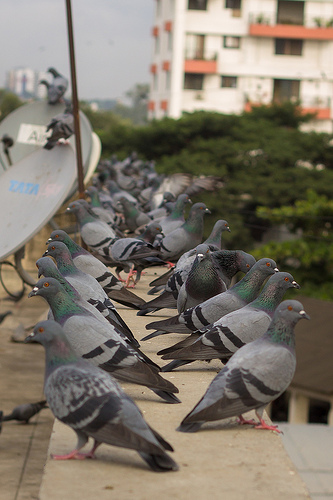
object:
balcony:
[183, 56, 218, 73]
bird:
[8, 320, 181, 473]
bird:
[36, 254, 161, 374]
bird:
[43, 240, 161, 370]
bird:
[45, 229, 149, 310]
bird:
[28, 278, 184, 404]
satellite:
[0, 96, 91, 287]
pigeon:
[141, 259, 281, 341]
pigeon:
[176, 243, 231, 317]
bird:
[175, 300, 309, 435]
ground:
[301, 116, 313, 135]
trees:
[183, 109, 328, 226]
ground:
[279, 123, 284, 134]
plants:
[247, 12, 332, 32]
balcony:
[251, 22, 332, 38]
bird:
[156, 270, 301, 371]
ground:
[252, 117, 274, 136]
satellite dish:
[0, 96, 86, 262]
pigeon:
[35, 66, 69, 106]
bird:
[176, 244, 227, 314]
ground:
[240, 48, 287, 77]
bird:
[96, 234, 167, 288]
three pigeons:
[143, 255, 304, 438]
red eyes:
[265, 261, 270, 267]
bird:
[26, 152, 310, 474]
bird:
[41, 100, 97, 150]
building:
[144, 0, 330, 141]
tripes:
[57, 391, 127, 440]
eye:
[284, 277, 288, 282]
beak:
[291, 280, 298, 284]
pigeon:
[35, 253, 128, 349]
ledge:
[36, 168, 309, 498]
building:
[0, 189, 331, 498]